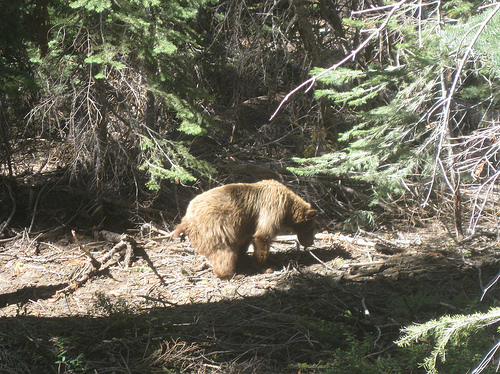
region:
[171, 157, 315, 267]
Brown bear in the woods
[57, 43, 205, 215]
Tree in the woods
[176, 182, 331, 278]
Bear squatting in the woods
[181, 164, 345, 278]
Brown bear looking down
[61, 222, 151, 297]
Log on the ground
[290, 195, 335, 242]
Bear looking at the ground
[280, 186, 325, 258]
Bear with its head bowed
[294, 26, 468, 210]
Pine Tree in the woods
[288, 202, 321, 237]
Bear with perked ears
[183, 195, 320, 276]
Bear preparing to sit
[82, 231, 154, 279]
huge branch on the ground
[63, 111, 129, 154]
bare leaves on the tree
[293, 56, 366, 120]
cluster of green leaves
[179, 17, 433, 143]
trees in the forest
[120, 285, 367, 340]
large shadow cast on the ground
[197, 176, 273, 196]
hump on bear's back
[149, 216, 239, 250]
small tail on bear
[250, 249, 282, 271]
bear's claw on the ground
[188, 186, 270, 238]
brown fur on bear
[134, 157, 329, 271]
large brown bear in the forest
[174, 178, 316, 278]
brown bear in the woods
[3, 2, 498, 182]
green pine tree leaves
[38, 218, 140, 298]
broken sticks on ground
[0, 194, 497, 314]
dry dirt light brown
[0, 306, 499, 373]
dry dead pine needles below ground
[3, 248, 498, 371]
shadows cast onto ground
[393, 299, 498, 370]
yellow pine needles on tree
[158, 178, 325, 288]
bear is going to bathroom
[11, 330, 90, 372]
green ferns bottom left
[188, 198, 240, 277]
bear has thick back legs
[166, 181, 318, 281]
Brown bear squatting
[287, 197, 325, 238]
Bear with its ears perked up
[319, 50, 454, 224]
Pine trees in the woods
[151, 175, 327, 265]
Bear look towards the ground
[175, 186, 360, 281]
Bear preparing to have a seat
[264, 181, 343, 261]
Bear looking towards the floor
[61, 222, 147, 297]
Tree branch on the ground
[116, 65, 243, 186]
Tree with brown limbs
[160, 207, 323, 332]
a bear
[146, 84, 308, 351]
a bear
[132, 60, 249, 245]
a bear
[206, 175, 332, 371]
a bear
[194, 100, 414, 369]
a bear